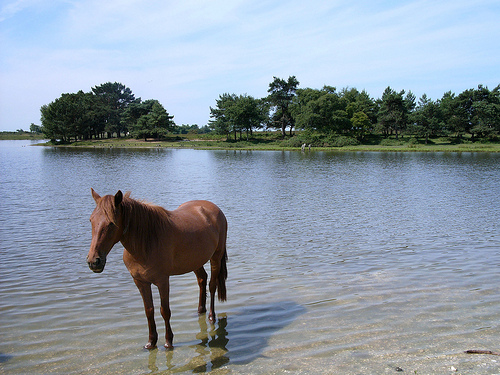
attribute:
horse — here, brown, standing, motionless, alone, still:
[88, 188, 229, 350]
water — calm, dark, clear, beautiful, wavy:
[0, 138, 500, 373]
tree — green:
[207, 105, 239, 141]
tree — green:
[127, 111, 169, 141]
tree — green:
[29, 97, 76, 146]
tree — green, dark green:
[267, 74, 300, 137]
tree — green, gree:
[350, 112, 375, 146]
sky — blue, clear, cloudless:
[0, 0, 499, 132]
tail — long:
[217, 239, 228, 302]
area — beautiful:
[2, 82, 498, 374]